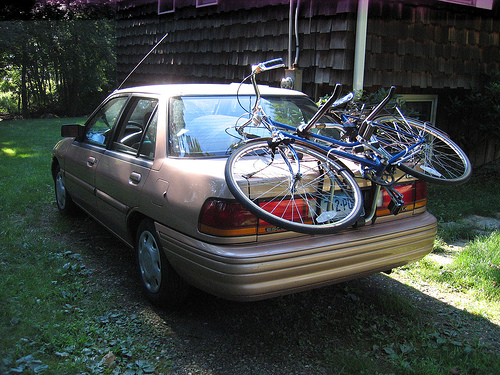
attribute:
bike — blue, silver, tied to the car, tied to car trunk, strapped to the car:
[225, 56, 474, 233]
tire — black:
[132, 221, 192, 316]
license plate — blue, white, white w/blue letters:
[317, 191, 369, 224]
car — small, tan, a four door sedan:
[53, 81, 439, 303]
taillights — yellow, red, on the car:
[196, 179, 435, 241]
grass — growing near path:
[2, 120, 500, 372]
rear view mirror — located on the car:
[148, 100, 161, 107]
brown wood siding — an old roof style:
[328, 33, 355, 50]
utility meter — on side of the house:
[280, 68, 302, 96]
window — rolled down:
[115, 94, 158, 155]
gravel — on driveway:
[74, 207, 447, 350]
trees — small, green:
[2, 5, 120, 123]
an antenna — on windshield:
[82, 31, 168, 109]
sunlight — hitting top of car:
[121, 78, 359, 154]